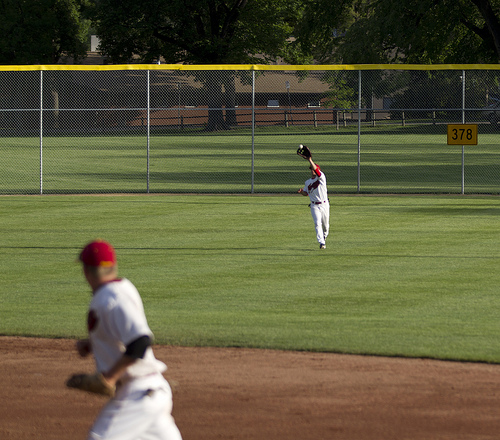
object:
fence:
[0, 62, 499, 193]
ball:
[298, 144, 303, 151]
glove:
[296, 145, 311, 160]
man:
[298, 150, 332, 250]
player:
[65, 241, 178, 440]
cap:
[80, 239, 117, 265]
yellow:
[1, 64, 499, 69]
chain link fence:
[1, 66, 500, 196]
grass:
[1, 117, 499, 363]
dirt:
[1, 335, 499, 439]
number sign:
[446, 123, 477, 145]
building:
[0, 31, 467, 125]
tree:
[1, 0, 94, 136]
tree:
[102, 3, 303, 135]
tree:
[280, 2, 397, 128]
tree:
[367, 0, 499, 120]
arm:
[306, 152, 324, 177]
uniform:
[303, 167, 332, 251]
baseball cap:
[313, 165, 320, 175]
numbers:
[450, 126, 473, 139]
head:
[78, 239, 119, 286]